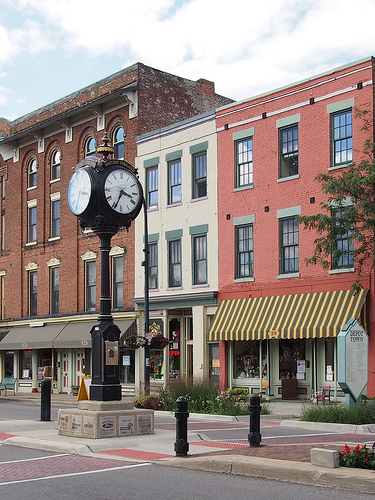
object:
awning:
[206, 287, 371, 343]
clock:
[67, 131, 144, 403]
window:
[278, 122, 299, 179]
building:
[215, 55, 374, 399]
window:
[191, 149, 207, 201]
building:
[134, 108, 218, 398]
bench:
[0, 377, 18, 397]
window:
[19, 350, 32, 380]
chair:
[317, 385, 331, 406]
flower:
[345, 444, 352, 454]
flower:
[354, 444, 359, 453]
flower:
[342, 450, 346, 455]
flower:
[363, 456, 368, 460]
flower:
[361, 444, 366, 448]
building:
[0, 60, 236, 397]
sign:
[169, 351, 180, 356]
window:
[50, 199, 60, 238]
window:
[27, 205, 36, 244]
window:
[27, 269, 38, 317]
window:
[27, 158, 36, 187]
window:
[51, 149, 61, 181]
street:
[0, 397, 375, 500]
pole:
[174, 396, 189, 457]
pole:
[248, 395, 262, 447]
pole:
[41, 380, 51, 421]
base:
[58, 400, 155, 439]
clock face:
[104, 168, 141, 215]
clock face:
[67, 169, 91, 215]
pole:
[90, 225, 121, 402]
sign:
[336, 317, 368, 407]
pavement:
[0, 397, 375, 500]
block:
[311, 448, 340, 468]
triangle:
[76, 378, 90, 401]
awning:
[0, 318, 137, 350]